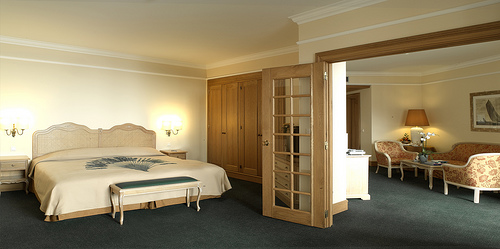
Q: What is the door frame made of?
A: Wood.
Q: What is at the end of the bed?
A: A table.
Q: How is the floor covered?
A: Carpeting.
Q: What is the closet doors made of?
A: Wood.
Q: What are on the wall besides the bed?
A: Lamps.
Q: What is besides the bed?
A: Night tables.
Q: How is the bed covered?
A: With a bedspread.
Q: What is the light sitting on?
A: A table.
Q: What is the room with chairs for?
A: Sitting.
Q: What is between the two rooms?
A: A door.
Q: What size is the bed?
A: King sized.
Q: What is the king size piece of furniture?
A: A bed.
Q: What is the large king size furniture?
A: A bed.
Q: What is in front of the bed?
A: A small table.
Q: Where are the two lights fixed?
A: On the wall.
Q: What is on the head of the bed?
A: A board.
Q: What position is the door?
A: Open.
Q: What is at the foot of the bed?
A: Bench.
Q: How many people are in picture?
A: None.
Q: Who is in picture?
A: No one.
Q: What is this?
A: A bedroom.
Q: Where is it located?
A: In a house.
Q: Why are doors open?
A: People using the area.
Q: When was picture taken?
A: During daylight.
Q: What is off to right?
A: A sitting room.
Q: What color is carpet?
A: Gray.